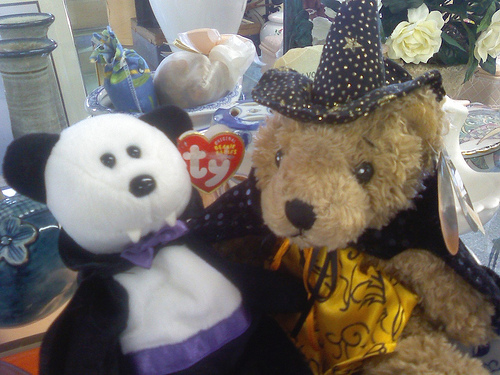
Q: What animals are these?
A: Bears.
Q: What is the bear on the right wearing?
A: A hat.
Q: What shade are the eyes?
A: Black.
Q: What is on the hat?
A: Stars.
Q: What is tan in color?
A: The bear.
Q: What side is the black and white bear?
A: On the left side.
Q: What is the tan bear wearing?
A: Dark blue wizard hat with yellow stars.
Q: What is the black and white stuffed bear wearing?
A: Vampire costume.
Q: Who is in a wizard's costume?
A: Brown stuffed bear.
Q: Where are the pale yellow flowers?
A: In teacup pot.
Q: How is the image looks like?
A: Good.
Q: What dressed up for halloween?
A: Beanie babie.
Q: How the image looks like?
A: Good.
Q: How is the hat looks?
A: Good.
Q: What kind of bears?
A: Beanie babies.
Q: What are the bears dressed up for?
A: Halloween.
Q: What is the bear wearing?
A: Cape.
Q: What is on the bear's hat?
A: Witch's hat.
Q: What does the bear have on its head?
A: A hat.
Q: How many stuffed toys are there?
A: Two.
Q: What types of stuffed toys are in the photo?
A: Bears.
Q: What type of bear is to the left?
A: A panda.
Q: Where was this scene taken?
A: The bedroom.